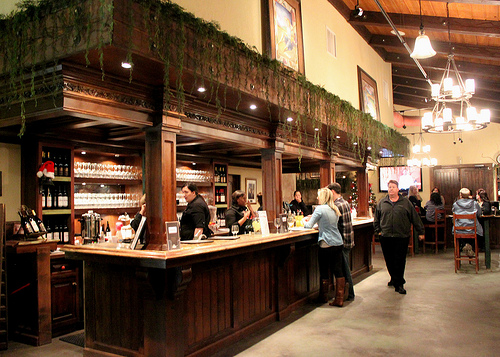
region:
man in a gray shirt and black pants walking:
[373, 180, 429, 296]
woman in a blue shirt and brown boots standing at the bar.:
[305, 185, 347, 307]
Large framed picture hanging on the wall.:
[260, 0, 307, 78]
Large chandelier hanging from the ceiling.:
[418, 55, 492, 136]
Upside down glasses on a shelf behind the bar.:
[72, 160, 139, 177]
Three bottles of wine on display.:
[15, 201, 47, 238]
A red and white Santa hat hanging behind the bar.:
[35, 160, 56, 180]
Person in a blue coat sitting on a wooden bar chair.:
[451, 186, 485, 273]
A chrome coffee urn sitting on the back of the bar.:
[76, 210, 105, 247]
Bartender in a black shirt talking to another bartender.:
[179, 181, 214, 239]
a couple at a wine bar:
[282, 171, 374, 321]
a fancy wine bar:
[50, 66, 430, 325]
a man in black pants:
[366, 169, 456, 298]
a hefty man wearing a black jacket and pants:
[371, 161, 452, 292]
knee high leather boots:
[321, 268, 352, 315]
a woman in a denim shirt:
[298, 178, 356, 323]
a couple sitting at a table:
[446, 173, 498, 275]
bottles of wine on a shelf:
[40, 149, 80, 262]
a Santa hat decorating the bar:
[31, 151, 58, 191]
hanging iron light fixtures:
[408, 20, 498, 152]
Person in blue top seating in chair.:
[449, 188, 484, 275]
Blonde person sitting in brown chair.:
[452, 186, 482, 275]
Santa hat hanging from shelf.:
[37, 151, 59, 183]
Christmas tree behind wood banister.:
[348, 159, 375, 219]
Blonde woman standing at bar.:
[303, 188, 345, 310]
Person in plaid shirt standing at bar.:
[329, 175, 354, 302]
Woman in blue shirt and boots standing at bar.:
[300, 187, 342, 310]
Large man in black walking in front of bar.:
[371, 176, 426, 298]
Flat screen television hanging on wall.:
[378, 163, 421, 194]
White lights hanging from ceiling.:
[412, 20, 493, 142]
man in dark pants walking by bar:
[373, 178, 423, 293]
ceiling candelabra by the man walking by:
[420, 50, 490, 131]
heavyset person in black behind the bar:
[177, 180, 207, 237]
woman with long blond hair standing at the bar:
[300, 185, 341, 305]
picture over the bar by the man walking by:
[356, 65, 378, 120]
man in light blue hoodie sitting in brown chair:
[450, 187, 482, 274]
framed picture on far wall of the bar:
[377, 164, 423, 194]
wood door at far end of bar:
[429, 163, 492, 200]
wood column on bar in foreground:
[144, 86, 194, 251]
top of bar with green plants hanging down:
[4, 1, 411, 154]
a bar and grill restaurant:
[0, 0, 499, 355]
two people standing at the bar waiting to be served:
[296, 185, 360, 307]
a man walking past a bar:
[369, 179, 426, 296]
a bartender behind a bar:
[176, 182, 214, 236]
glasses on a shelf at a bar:
[74, 160, 143, 180]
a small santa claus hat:
[36, 157, 57, 179]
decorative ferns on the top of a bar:
[2, 1, 407, 161]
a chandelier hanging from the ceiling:
[415, 55, 490, 135]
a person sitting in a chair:
[450, 185, 482, 271]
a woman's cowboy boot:
[329, 276, 347, 308]